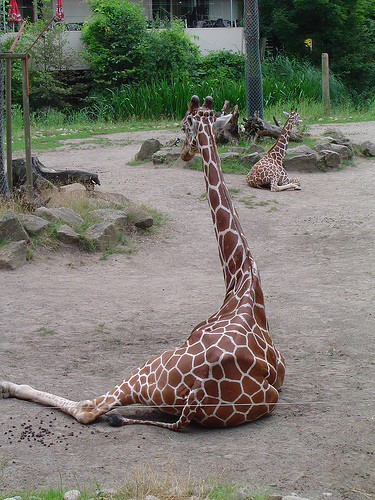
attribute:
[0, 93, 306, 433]
giraffes — laying down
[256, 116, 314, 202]
giraffe — baby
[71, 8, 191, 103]
tree — tall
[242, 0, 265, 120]
tree trunk — tall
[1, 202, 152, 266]
rocks — medium sized, landscaping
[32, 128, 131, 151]
grass — sparse, green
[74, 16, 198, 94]
bush — large, green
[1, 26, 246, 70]
wall — white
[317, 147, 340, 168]
rock — big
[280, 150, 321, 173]
rock — big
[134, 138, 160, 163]
rock — big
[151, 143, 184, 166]
rock — big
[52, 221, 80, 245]
rock — big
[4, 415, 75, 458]
droppings — brown, animal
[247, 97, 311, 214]
giraffe — baby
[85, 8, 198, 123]
bushes — tall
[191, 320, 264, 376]
pattern — brown, white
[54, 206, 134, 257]
rock — large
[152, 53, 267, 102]
plants — green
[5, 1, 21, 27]
umbrella — red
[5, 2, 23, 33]
umbrella — red, white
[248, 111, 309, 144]
tree stump — dead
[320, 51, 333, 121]
post —  Solid wooden,  for fence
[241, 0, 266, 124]
fence — grey, chain link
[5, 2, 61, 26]
umbrellas — red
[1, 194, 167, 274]
grass —  green 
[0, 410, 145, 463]
pellets — Giraffe's , of dung 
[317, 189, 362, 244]
dirt — grey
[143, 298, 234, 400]
lines — white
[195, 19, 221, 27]
furniture —  for Patio